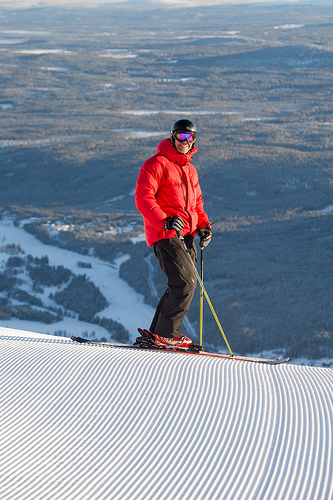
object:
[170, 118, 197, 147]
helmet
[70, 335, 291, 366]
skis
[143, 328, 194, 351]
ski boot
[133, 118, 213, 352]
man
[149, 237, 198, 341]
pants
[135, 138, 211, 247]
jacket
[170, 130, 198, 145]
goggles